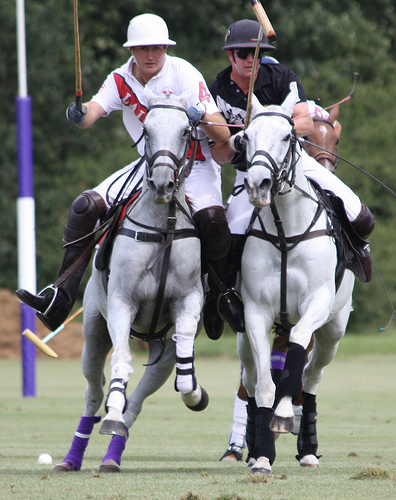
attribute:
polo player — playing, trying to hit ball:
[207, 16, 325, 152]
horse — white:
[222, 83, 368, 476]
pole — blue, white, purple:
[8, 1, 49, 402]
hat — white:
[118, 10, 188, 51]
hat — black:
[216, 17, 288, 55]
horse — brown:
[295, 78, 359, 468]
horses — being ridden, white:
[45, 85, 380, 475]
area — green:
[0, 351, 393, 496]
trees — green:
[1, 3, 392, 334]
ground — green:
[1, 456, 390, 499]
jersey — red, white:
[88, 49, 223, 178]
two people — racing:
[59, 9, 371, 240]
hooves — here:
[49, 333, 336, 477]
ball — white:
[34, 449, 56, 474]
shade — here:
[0, 445, 263, 483]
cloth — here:
[107, 66, 215, 140]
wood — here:
[236, 8, 277, 131]